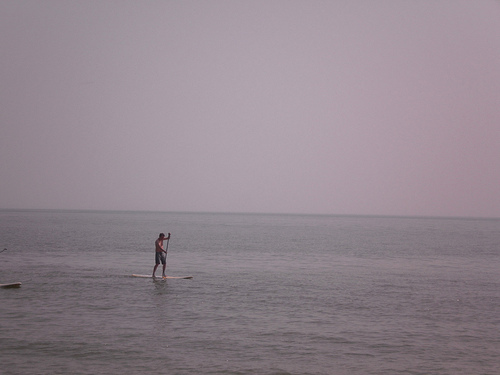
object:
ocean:
[229, 227, 500, 375]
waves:
[299, 289, 369, 316]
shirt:
[155, 237, 170, 253]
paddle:
[164, 233, 172, 261]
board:
[132, 274, 193, 279]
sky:
[15, 11, 491, 103]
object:
[0, 281, 21, 287]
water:
[37, 292, 98, 337]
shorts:
[155, 251, 167, 264]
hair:
[158, 233, 165, 237]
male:
[152, 231, 172, 278]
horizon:
[0, 208, 499, 223]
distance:
[58, 173, 183, 193]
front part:
[182, 276, 194, 279]